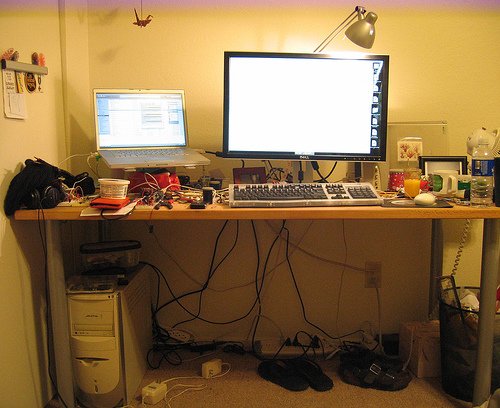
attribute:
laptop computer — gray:
[92, 84, 212, 170]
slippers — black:
[262, 347, 334, 387]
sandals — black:
[338, 346, 411, 390]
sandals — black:
[257, 355, 332, 390]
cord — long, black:
[282, 226, 363, 343]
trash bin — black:
[426, 272, 481, 382]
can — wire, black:
[422, 265, 497, 404]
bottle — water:
[473, 137, 493, 204]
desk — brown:
[17, 153, 498, 240]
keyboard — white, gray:
[222, 176, 385, 211]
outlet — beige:
[363, 261, 383, 291]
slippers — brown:
[337, 352, 409, 391]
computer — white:
[72, 254, 165, 406]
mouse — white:
[412, 191, 436, 207]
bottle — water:
[479, 99, 485, 203]